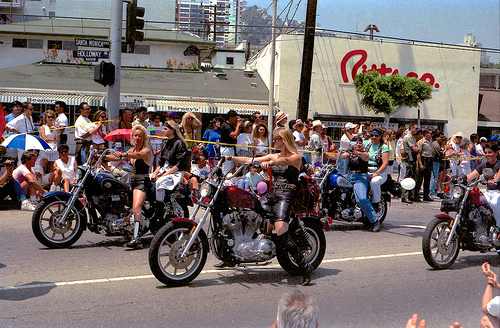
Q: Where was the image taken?
A: It was taken at the street.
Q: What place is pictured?
A: It is a street.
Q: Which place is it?
A: It is a street.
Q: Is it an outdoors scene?
A: Yes, it is outdoors.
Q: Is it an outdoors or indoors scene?
A: It is outdoors.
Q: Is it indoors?
A: No, it is outdoors.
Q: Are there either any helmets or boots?
A: Yes, there are boots.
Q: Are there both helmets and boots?
A: No, there are boots but no helmets.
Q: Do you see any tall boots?
A: Yes, there are tall boots.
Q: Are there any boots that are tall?
A: Yes, there are boots that are tall.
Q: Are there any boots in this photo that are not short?
A: Yes, there are tall boots.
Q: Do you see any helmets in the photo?
A: No, there are no helmets.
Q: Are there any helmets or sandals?
A: No, there are no helmets or sandals.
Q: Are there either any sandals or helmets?
A: No, there are no helmets or sandals.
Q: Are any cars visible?
A: No, there are no cars.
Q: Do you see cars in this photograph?
A: No, there are no cars.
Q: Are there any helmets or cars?
A: No, there are no cars or helmets.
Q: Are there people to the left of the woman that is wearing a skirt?
A: Yes, there is a person to the left of the woman.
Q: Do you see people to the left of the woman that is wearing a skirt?
A: Yes, there is a person to the left of the woman.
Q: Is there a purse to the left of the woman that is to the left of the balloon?
A: No, there is a person to the left of the woman.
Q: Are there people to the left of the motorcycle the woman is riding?
A: Yes, there is a person to the left of the motorcycle.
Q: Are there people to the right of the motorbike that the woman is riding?
A: No, the person is to the left of the motorbike.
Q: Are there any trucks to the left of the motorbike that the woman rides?
A: No, there is a person to the left of the motorbike.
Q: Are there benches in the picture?
A: No, there are no benches.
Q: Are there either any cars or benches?
A: No, there are no benches or cars.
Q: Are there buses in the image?
A: No, there are no buses.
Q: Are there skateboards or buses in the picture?
A: No, there are no buses or skateboards.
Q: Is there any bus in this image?
A: No, there are no buses.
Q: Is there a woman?
A: Yes, there is a woman.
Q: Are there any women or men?
A: Yes, there is a woman.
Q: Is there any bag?
A: No, there are no bags.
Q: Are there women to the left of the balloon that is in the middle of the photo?
A: Yes, there is a woman to the left of the balloon.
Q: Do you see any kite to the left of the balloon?
A: No, there is a woman to the left of the balloon.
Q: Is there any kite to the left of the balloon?
A: No, there is a woman to the left of the balloon.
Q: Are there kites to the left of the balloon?
A: No, there is a woman to the left of the balloon.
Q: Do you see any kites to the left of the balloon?
A: No, there is a woman to the left of the balloon.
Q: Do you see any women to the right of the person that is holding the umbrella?
A: Yes, there is a woman to the right of the person.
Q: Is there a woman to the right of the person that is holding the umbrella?
A: Yes, there is a woman to the right of the person.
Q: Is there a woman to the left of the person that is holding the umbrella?
A: No, the woman is to the right of the person.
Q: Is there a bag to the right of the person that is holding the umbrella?
A: No, there is a woman to the right of the person.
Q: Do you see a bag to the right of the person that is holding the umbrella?
A: No, there is a woman to the right of the person.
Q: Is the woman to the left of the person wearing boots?
A: Yes, the woman is wearing boots.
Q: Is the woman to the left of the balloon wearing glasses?
A: No, the woman is wearing boots.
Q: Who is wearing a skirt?
A: The woman is wearing a skirt.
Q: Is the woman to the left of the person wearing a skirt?
A: Yes, the woman is wearing a skirt.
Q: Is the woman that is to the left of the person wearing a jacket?
A: No, the woman is wearing a skirt.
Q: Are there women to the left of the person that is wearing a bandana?
A: Yes, there is a woman to the left of the person.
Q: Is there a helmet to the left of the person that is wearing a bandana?
A: No, there is a woman to the left of the person.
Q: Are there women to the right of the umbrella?
A: Yes, there is a woman to the right of the umbrella.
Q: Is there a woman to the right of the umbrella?
A: Yes, there is a woman to the right of the umbrella.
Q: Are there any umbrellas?
A: Yes, there is an umbrella.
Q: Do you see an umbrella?
A: Yes, there is an umbrella.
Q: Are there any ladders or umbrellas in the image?
A: Yes, there is an umbrella.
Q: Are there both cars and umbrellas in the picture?
A: No, there is an umbrella but no cars.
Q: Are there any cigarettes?
A: No, there are no cigarettes.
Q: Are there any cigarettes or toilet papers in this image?
A: No, there are no cigarettes or toilet papers.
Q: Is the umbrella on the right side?
A: No, the umbrella is on the left of the image.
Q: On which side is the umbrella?
A: The umbrella is on the left of the image.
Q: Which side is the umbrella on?
A: The umbrella is on the left of the image.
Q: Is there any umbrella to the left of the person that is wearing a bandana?
A: Yes, there is an umbrella to the left of the person.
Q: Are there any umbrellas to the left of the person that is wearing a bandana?
A: Yes, there is an umbrella to the left of the person.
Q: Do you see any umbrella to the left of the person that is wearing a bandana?
A: Yes, there is an umbrella to the left of the person.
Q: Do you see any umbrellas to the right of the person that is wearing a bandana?
A: No, the umbrella is to the left of the person.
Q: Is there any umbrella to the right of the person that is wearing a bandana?
A: No, the umbrella is to the left of the person.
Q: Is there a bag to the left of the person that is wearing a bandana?
A: No, there is an umbrella to the left of the person.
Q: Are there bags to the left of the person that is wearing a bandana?
A: No, there is an umbrella to the left of the person.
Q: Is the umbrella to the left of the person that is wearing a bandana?
A: Yes, the umbrella is to the left of the person.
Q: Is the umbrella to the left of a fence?
A: No, the umbrella is to the left of the person.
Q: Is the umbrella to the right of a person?
A: No, the umbrella is to the left of a person.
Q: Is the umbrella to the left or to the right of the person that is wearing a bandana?
A: The umbrella is to the left of the person.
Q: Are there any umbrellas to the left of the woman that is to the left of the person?
A: Yes, there is an umbrella to the left of the woman.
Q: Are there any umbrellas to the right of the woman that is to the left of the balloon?
A: No, the umbrella is to the left of the woman.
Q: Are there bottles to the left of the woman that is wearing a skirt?
A: No, there is an umbrella to the left of the woman.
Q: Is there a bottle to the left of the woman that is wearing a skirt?
A: No, there is an umbrella to the left of the woman.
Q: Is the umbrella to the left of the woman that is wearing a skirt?
A: Yes, the umbrella is to the left of the woman.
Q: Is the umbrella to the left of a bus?
A: No, the umbrella is to the left of the woman.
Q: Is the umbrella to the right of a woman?
A: No, the umbrella is to the left of a woman.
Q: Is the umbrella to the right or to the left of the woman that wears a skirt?
A: The umbrella is to the left of the woman.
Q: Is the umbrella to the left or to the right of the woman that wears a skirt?
A: The umbrella is to the left of the woman.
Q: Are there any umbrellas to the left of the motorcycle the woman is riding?
A: Yes, there is an umbrella to the left of the motorcycle.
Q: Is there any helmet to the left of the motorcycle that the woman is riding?
A: No, there is an umbrella to the left of the motorcycle.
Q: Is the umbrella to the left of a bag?
A: No, the umbrella is to the left of the motorcycle.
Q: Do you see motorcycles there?
A: Yes, there is a motorcycle.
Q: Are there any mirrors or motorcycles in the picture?
A: Yes, there is a motorcycle.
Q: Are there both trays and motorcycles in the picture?
A: No, there is a motorcycle but no trays.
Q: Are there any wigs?
A: No, there are no wigs.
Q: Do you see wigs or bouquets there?
A: No, there are no wigs or bouquets.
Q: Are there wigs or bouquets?
A: No, there are no wigs or bouquets.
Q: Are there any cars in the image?
A: No, there are no cars.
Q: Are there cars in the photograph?
A: No, there are no cars.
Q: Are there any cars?
A: No, there are no cars.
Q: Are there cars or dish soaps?
A: No, there are no cars or dish soaps.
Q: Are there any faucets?
A: No, there are no faucets.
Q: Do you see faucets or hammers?
A: No, there are no faucets or hammers.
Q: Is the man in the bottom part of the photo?
A: Yes, the man is in the bottom of the image.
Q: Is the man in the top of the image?
A: No, the man is in the bottom of the image.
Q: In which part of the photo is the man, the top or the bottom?
A: The man is in the bottom of the image.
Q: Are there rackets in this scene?
A: No, there are no rackets.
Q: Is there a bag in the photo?
A: No, there are no bags.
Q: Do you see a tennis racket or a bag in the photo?
A: No, there are no bags or rackets.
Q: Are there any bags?
A: No, there are no bags.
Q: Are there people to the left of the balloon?
A: Yes, there is a person to the left of the balloon.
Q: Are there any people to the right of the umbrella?
A: Yes, there is a person to the right of the umbrella.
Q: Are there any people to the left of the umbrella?
A: No, the person is to the right of the umbrella.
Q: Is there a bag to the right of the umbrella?
A: No, there is a person to the right of the umbrella.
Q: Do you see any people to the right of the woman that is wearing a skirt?
A: Yes, there is a person to the right of the woman.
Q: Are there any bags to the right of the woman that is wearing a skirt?
A: No, there is a person to the right of the woman.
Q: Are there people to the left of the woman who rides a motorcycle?
A: Yes, there is a person to the left of the woman.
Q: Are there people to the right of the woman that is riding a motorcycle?
A: No, the person is to the left of the woman.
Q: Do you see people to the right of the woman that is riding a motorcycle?
A: No, the person is to the left of the woman.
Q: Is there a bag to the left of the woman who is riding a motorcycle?
A: No, there is a person to the left of the woman.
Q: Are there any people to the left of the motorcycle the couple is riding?
A: Yes, there is a person to the left of the motorbike.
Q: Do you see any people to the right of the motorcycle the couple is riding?
A: No, the person is to the left of the motorcycle.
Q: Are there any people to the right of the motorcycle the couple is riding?
A: No, the person is to the left of the motorcycle.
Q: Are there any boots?
A: Yes, there are boots.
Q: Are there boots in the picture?
A: Yes, there are boots.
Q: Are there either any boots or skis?
A: Yes, there are boots.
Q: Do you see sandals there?
A: No, there are no sandals.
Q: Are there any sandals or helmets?
A: No, there are no sandals or helmets.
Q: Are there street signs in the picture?
A: Yes, there is a street sign.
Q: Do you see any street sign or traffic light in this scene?
A: Yes, there is a street sign.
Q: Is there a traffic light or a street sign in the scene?
A: Yes, there is a street sign.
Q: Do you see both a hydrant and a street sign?
A: No, there is a street sign but no fire hydrants.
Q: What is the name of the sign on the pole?
A: The sign is a street sign.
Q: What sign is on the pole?
A: The sign is a street sign.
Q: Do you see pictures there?
A: No, there are no pictures.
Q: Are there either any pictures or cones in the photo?
A: No, there are no pictures or cones.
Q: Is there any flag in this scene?
A: No, there are no flags.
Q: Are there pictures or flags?
A: No, there are no flags or pictures.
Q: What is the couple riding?
A: The couple is riding a motorcycle.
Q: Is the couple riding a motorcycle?
A: Yes, the couple is riding a motorcycle.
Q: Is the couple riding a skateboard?
A: No, the couple is riding a motorcycle.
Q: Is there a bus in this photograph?
A: No, there are no buses.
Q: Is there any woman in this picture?
A: Yes, there is a woman.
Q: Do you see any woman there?
A: Yes, there is a woman.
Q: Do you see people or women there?
A: Yes, there is a woman.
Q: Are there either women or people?
A: Yes, there is a woman.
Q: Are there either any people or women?
A: Yes, there is a woman.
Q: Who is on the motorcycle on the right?
A: The woman is on the motorbike.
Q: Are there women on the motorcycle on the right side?
A: Yes, there is a woman on the motorbike.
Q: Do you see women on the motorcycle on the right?
A: Yes, there is a woman on the motorbike.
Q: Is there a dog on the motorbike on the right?
A: No, there is a woman on the motorcycle.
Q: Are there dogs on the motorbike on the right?
A: No, there is a woman on the motorcycle.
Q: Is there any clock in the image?
A: No, there are no clocks.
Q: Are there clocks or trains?
A: No, there are no clocks or trains.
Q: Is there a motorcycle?
A: Yes, there is a motorcycle.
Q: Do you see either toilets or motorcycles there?
A: Yes, there is a motorcycle.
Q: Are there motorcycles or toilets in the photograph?
A: Yes, there is a motorcycle.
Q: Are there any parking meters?
A: No, there are no parking meters.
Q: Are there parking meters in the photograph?
A: No, there are no parking meters.